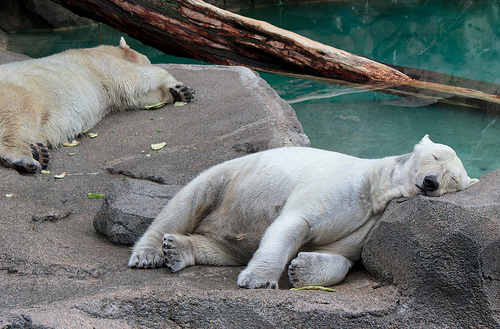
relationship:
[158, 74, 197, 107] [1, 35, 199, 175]
black paws of bear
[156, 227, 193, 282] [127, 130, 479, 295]
paw of bear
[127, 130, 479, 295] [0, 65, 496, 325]
bear laying on ground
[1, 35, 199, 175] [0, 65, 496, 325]
bear laying on ground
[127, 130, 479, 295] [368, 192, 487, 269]
bear laying on rock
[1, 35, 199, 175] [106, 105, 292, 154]
bear laying on rock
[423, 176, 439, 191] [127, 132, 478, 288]
nose on bear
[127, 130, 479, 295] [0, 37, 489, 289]
bear are taking a nap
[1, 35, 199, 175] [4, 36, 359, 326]
bear laying on rock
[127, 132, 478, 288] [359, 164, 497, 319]
bear laying on rock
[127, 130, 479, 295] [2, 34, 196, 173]
bear in front of bears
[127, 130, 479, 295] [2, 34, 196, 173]
bear near bears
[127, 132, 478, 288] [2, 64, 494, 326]
bear resting on rocks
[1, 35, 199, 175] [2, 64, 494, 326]
bear resting on rocks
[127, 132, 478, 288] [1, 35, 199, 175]
bear near bear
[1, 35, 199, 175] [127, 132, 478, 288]
bear behind bear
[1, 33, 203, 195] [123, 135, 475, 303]
bear behind bear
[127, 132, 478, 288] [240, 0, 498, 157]
bear near water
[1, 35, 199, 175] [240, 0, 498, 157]
bear near water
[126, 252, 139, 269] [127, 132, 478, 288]
toes on bear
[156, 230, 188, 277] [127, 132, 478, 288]
toes on bear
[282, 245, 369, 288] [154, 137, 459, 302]
paw on bear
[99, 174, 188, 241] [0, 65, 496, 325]
rock on ground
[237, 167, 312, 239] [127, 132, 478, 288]
fur on bear